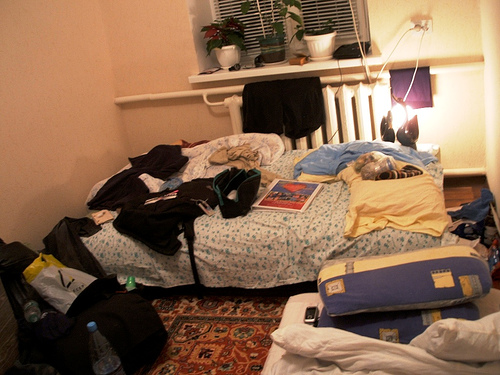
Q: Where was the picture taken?
A: In a bedroom.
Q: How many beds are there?
A: One.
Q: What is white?
A: Walls.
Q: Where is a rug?
A: On the floor.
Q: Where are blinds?
A: On the window.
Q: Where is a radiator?
A: Against the wall.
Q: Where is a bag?
A: On the bed.